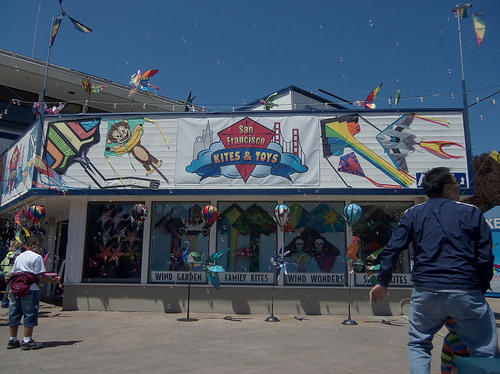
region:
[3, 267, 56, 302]
Boy is wearing fanny pack.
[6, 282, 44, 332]
Boy is wearing jean shorts.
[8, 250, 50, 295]
Boy is wearing white shirt.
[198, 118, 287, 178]
Sign reads San Fransisco Kites & Toys.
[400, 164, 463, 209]
Man has short hair.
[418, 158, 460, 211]
Man has dark hair.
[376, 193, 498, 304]
Man is wearing jacket.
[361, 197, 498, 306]
Man's jacket is blue.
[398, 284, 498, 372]
Man is wearing blue jeans.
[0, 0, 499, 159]
The sky is blue and clear.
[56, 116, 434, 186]
colorful sign on front of store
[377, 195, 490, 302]
wrinkled blue jacket on man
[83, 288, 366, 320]
shadows on bottom of building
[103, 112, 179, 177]
monkey on store sign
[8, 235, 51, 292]
person in white tee shirt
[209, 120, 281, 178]
name of store on sign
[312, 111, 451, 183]
kites on store sign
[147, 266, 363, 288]
signs in store windows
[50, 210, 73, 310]
door in front of store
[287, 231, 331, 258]
two skulls on sign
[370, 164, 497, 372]
The man in the blue shirt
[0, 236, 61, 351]
The person in the white shirt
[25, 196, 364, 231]
The balls in front of the shop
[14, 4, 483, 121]
The bubbles in the sky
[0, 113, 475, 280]
The front of the building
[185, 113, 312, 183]
The sign of the stores name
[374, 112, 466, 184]
The painted kite that looks like a jet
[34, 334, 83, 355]
The shadow of the boy in white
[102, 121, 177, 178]
The monkey with a banana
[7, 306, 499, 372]
The sidewalk in front of the store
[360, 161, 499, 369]
a man wearing jeans and a blue shirt looking upward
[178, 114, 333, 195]
a colorful sign on the building with the name of the business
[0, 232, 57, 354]
a woman standing with a white shirt and a maroon jacket around her waist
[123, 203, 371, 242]
several balloons hanging in front of the store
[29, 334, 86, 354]
a shadow of the lady on the ground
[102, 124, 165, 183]
a picture of a monkey with a banana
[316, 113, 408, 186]
a picture of a rainbow colored kite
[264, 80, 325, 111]
the corner of a white building in the background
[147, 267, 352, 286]
white signs with black lettering in the windows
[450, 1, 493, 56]
two small rainbow flags on top of a pole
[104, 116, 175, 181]
caricture of a monkey eating a banana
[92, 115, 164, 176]
caricture of a monkey eating a banana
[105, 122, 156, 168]
caricture of a monkey eating a banana